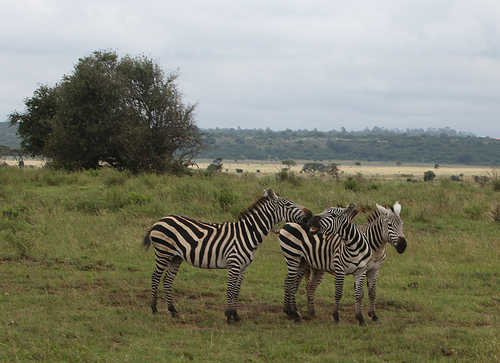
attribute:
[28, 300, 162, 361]
grass — green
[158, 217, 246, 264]
stripes — black, white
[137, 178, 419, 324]
zebras — striped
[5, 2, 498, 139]
clouds — white, puffy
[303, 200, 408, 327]
zebra — looking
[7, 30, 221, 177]
tree — distant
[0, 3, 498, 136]
sky — dark , cloudy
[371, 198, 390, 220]
ear — white